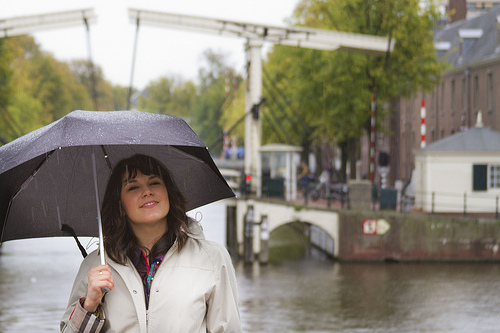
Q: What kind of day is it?
A: Rainy.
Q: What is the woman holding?
A: Umbrella.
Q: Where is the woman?
A: Edge of a canal.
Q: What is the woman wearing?
A: Jacket.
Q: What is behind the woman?
A: Bridge.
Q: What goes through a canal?
A: Boat.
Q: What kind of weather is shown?
A: Raining.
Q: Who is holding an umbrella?
A: A lady.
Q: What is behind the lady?
A: A river.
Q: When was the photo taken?
A: During the day.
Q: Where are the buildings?
A: Across the water.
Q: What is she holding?
A: An umbrella.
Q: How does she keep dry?
A: Umbrella and rain jacket.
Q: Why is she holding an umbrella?
A: To stay dry in the rain.